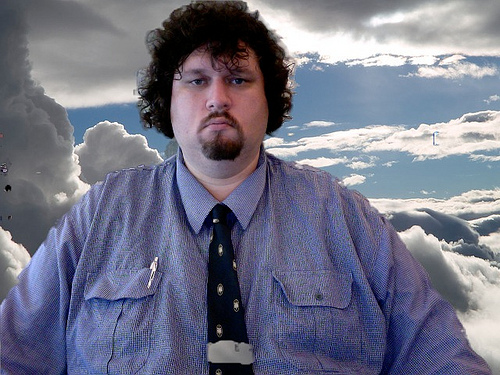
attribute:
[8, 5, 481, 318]
cloud — part  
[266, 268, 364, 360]
pocket — edge 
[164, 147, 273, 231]
collar — part 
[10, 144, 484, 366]
shirt —  blue button down, part , blue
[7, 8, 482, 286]
sky — part , blue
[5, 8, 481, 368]
man — dark haired, one, light skinned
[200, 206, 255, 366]
tie — patterned, dark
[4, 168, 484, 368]
shirt — button down, blue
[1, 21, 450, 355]
man — dark, caucasian, one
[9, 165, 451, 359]
shirt — blue, button down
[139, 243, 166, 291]
pen — shiny silver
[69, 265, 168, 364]
pocket — shirt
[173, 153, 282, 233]
collar — one, blue, shirt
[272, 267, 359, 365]
pocket — shirt, one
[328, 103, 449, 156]
clouds — sunlit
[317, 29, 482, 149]
sky — blue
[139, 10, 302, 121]
hair — curly